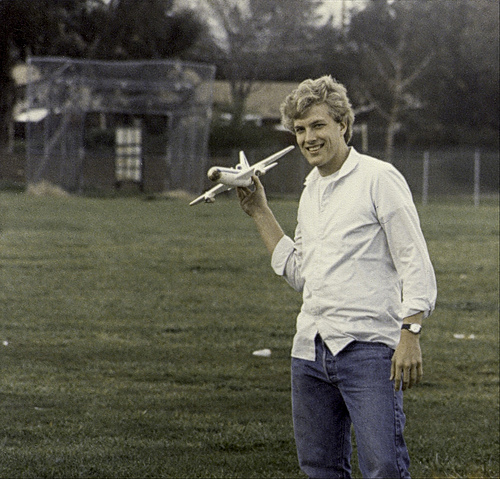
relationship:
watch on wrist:
[403, 322, 424, 333] [399, 324, 425, 339]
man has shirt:
[237, 74, 438, 478] [268, 147, 437, 361]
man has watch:
[237, 74, 438, 478] [403, 322, 424, 333]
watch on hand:
[403, 322, 424, 333] [390, 337, 423, 389]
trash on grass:
[254, 349, 273, 357] [1, 191, 498, 478]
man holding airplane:
[237, 74, 438, 478] [189, 146, 295, 208]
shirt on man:
[268, 147, 437, 361] [237, 74, 438, 478]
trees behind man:
[1, 1, 500, 193] [237, 74, 438, 478]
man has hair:
[237, 74, 438, 478] [280, 74, 353, 144]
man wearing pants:
[237, 74, 438, 478] [290, 334, 413, 478]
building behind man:
[34, 78, 394, 190] [237, 74, 438, 478]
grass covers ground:
[1, 191, 498, 478] [1, 190, 499, 479]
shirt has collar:
[268, 147, 437, 361] [303, 146, 360, 185]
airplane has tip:
[189, 146, 295, 208] [209, 167, 220, 179]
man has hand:
[237, 74, 438, 478] [390, 337, 423, 389]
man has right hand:
[237, 74, 438, 478] [239, 175, 267, 214]